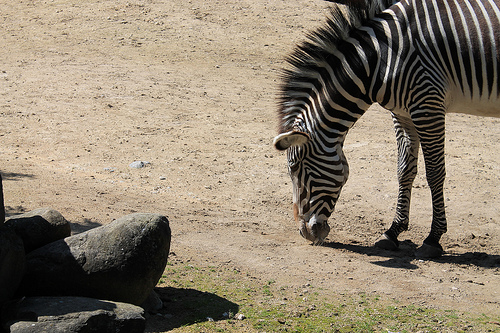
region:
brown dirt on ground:
[124, 110, 215, 160]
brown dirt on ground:
[43, 95, 83, 127]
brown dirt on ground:
[102, 58, 167, 95]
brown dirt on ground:
[178, 61, 234, 91]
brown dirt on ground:
[196, 38, 273, 101]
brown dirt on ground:
[40, 29, 97, 60]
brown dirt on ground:
[109, 50, 212, 82]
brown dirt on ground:
[193, 37, 238, 73]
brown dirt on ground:
[6, 164, 55, 187]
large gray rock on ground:
[76, 218, 187, 263]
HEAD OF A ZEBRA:
[281, 89, 360, 238]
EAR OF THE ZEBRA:
[268, 129, 318, 161]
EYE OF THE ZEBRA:
[285, 156, 298, 187]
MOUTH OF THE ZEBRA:
[288, 206, 334, 238]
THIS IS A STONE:
[92, 217, 162, 291]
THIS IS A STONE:
[73, 302, 118, 332]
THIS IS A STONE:
[12, 207, 73, 237]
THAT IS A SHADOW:
[155, 289, 227, 316]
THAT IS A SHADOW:
[366, 245, 498, 263]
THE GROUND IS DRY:
[133, 107, 197, 158]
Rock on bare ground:
[120, 157, 150, 173]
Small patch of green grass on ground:
[141, 283, 489, 330]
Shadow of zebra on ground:
[324, 234, 499, 274]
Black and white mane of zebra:
[277, 1, 382, 136]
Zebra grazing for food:
[276, 0, 497, 248]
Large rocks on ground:
[4, 196, 174, 331]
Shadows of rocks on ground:
[8, 215, 238, 331]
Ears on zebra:
[272, 126, 309, 156]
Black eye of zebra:
[285, 157, 305, 174]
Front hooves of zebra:
[366, 233, 449, 260]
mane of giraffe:
[271, 2, 381, 129]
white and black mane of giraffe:
[269, 1, 385, 124]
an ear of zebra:
[266, 125, 308, 153]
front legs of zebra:
[369, 111, 454, 267]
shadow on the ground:
[329, 232, 499, 274]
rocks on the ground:
[1, 201, 182, 326]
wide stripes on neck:
[326, 16, 388, 106]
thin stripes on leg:
[406, 62, 453, 259]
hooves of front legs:
[366, 232, 448, 261]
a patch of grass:
[132, 252, 496, 332]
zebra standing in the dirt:
[257, 4, 499, 265]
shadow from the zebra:
[324, 234, 497, 276]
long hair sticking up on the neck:
[261, 3, 371, 120]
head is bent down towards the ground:
[262, 33, 357, 258]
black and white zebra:
[242, 3, 499, 268]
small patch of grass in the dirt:
[162, 245, 358, 330]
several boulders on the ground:
[1, 203, 187, 329]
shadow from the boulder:
[147, 275, 238, 331]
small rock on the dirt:
[128, 156, 144, 172]